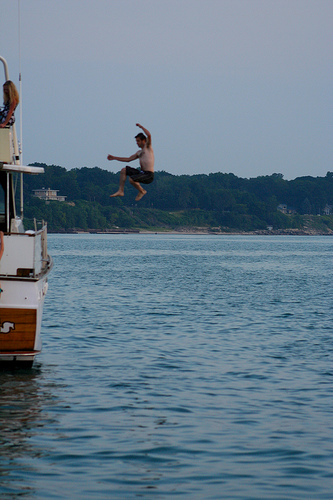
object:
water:
[0, 232, 333, 500]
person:
[107, 123, 155, 201]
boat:
[0, 0, 55, 363]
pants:
[125, 165, 154, 185]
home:
[32, 187, 68, 205]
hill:
[100, 205, 139, 226]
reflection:
[0, 361, 70, 499]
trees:
[226, 198, 228, 203]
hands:
[107, 153, 114, 161]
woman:
[0, 80, 19, 128]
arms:
[113, 149, 141, 163]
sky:
[0, 0, 333, 180]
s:
[0, 319, 16, 335]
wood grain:
[0, 308, 38, 352]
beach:
[73, 221, 333, 235]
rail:
[33, 216, 52, 281]